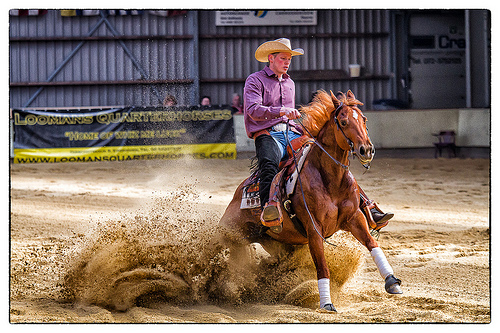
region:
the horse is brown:
[241, 48, 439, 321]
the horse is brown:
[234, 108, 370, 303]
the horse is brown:
[228, 68, 317, 285]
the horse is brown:
[208, 29, 337, 229]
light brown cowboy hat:
[256, 36, 303, 64]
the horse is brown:
[228, 189, 315, 322]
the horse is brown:
[293, 122, 428, 304]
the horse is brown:
[207, 107, 294, 315]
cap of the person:
[248, 27, 308, 59]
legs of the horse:
[297, 234, 433, 310]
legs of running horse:
[288, 240, 427, 327]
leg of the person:
[255, 132, 285, 187]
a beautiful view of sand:
[81, 192, 261, 316]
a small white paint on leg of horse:
[314, 274, 340, 310]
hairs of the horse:
[296, 92, 354, 134]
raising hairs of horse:
[300, 92, 345, 141]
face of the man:
[262, 48, 295, 81]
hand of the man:
[249, 95, 310, 131]